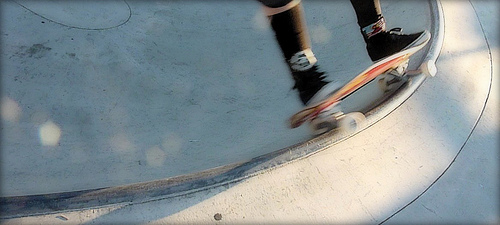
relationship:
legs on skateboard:
[256, 1, 431, 105] [287, 29, 438, 134]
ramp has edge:
[0, 2, 445, 217] [0, 44, 444, 212]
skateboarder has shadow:
[257, 0, 431, 129] [13, 139, 305, 223]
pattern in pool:
[20, 0, 132, 33] [0, 2, 445, 217]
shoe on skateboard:
[289, 62, 346, 104] [287, 29, 438, 134]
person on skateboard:
[257, 0, 431, 129] [287, 29, 438, 134]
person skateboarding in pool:
[257, 0, 431, 129] [0, 2, 445, 217]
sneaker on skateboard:
[366, 28, 430, 62] [287, 29, 438, 134]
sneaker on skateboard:
[289, 62, 346, 104] [287, 29, 438, 134]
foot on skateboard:
[281, 49, 342, 105] [287, 29, 438, 134]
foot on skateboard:
[363, 26, 431, 63] [287, 29, 438, 134]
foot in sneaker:
[281, 49, 342, 105] [289, 62, 346, 104]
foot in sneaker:
[363, 26, 431, 63] [366, 28, 430, 62]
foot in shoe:
[281, 49, 342, 105] [289, 62, 346, 104]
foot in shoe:
[363, 26, 431, 63] [366, 28, 430, 62]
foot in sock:
[281, 49, 342, 105] [266, 2, 312, 59]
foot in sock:
[363, 26, 431, 63] [352, 0, 384, 25]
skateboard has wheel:
[287, 29, 438, 134] [310, 113, 345, 141]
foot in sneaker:
[281, 49, 342, 105] [366, 28, 430, 62]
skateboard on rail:
[287, 29, 438, 134] [0, 125, 425, 213]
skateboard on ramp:
[287, 29, 438, 134] [0, 2, 445, 217]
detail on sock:
[289, 47, 320, 69] [266, 2, 312, 59]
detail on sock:
[361, 16, 388, 35] [352, 0, 384, 25]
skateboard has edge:
[287, 29, 438, 134] [0, 44, 444, 212]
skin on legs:
[261, 0, 305, 18] [256, 1, 431, 105]